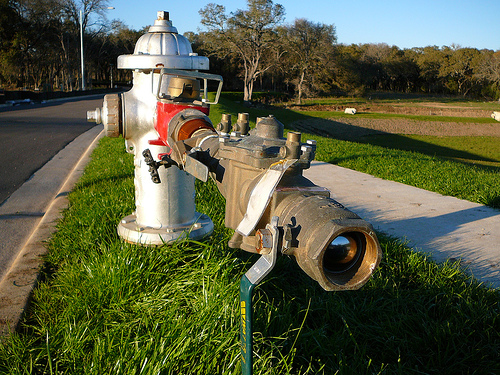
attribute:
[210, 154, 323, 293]
fire extinguisher — silver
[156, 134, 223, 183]
hose attachment — large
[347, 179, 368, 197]
sidewalk — white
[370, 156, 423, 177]
grass — path, ground, green, patch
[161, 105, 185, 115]
tape — red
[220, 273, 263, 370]
handle — green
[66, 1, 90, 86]
lamp — tall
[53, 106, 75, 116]
road — single, paved, grey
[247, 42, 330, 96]
trees — pictured, forest, row, here, green, old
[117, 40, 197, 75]
hydrant — silver, red, fire, here, painted, metal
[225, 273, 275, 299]
lever — green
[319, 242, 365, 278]
opening — round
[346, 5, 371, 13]
sky — clear, blue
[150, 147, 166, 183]
valve — black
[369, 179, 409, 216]
pavement — stone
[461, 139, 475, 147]
field — here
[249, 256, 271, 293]
stake — metal